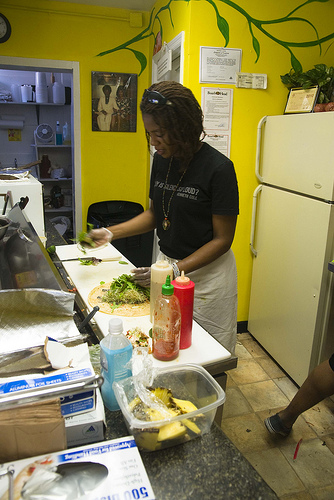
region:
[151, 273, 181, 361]
a bottle of hot sauce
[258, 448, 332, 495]
tile flooring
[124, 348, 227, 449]
pineapple slices in a plastic dish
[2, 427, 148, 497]
a box of plastic bags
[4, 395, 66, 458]
brown paper bags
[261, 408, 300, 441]
a foot wearing a shoe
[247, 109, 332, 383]
a refridgerator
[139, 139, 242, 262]
a woman wearing a black shirt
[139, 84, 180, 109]
sunglasses atop a head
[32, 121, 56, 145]
a fan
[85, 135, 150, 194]
the wall is yellow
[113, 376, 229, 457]
pineapples in the container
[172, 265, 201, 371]
the bottle is red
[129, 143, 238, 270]
the shirt is black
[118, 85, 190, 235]
the woman is wearing a necklage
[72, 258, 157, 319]
the leaves are green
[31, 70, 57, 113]
the cups are white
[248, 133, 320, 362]
the refrigerator door is closed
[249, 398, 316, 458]
the shoe is black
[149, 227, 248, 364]
the apron is beige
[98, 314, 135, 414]
bottled water with blue label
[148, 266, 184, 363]
nearly empty bottle of red sauce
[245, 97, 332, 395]
white residential refrigerator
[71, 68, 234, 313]
black woman preparing food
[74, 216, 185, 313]
two hands wearing plastic gloves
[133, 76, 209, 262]
woman wearing long necklace over black T-shirt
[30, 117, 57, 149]
little round white fan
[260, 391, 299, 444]
blue sneakered foot lifting up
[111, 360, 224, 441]
large pineapple chunks in plastic container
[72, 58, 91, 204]
white wooden door trim against a yellow painted wall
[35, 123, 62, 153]
fan on the shelf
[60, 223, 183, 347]
vegetables on a tortilla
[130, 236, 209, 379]
condiments in the bottles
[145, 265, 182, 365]
the sauce bottle is almost empty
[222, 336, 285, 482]
the floor is tiled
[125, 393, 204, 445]
the pineapple is yellow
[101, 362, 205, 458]
the container is transparent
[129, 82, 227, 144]
the sunglasses is on the head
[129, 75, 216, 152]
the hair is brown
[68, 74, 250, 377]
a woman preparing a wrap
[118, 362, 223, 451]
a container of pineapple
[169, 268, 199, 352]
a red squirt bottle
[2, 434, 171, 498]
a box of gloves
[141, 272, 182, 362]
an almost empty bottle of hot sauce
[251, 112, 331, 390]
the white refrigerator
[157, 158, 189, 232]
the woman's necklace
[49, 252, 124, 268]
the knife on the cutting board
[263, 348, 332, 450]
the foot of another person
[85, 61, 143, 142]
a photo of two people on the wall